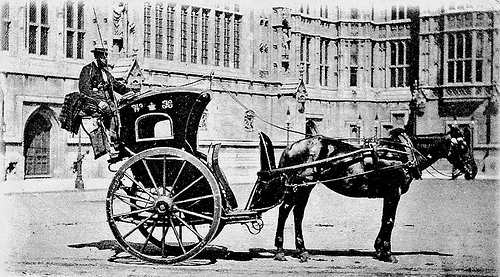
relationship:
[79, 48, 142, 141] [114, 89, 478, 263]
man riding horse carriage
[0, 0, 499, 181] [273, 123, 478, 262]
building behind brown horse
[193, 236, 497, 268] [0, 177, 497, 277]
shadow on floor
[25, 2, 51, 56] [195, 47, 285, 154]
window on wall.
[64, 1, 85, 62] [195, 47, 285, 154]
window on wall.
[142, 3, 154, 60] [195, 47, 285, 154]
window on wall.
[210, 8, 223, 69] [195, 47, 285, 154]
window on wall.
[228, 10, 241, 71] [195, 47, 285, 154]
window on wall.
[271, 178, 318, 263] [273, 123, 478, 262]
legs on brown horse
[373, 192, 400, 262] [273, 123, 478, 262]
legs on brown horse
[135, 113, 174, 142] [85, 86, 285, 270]
window on wagon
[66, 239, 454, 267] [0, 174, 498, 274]
shadow on floor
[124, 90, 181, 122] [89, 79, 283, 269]
numbers on carriage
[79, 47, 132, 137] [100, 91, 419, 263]
man sitting on carriage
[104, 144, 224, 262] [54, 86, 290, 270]
wheel on carriage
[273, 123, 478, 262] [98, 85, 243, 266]
brown horse attached to carriage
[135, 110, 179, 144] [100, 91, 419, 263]
window on carriage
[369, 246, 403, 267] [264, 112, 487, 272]
hoof on horse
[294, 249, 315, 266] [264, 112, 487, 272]
hoof on horse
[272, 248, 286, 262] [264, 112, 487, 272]
hoof on horse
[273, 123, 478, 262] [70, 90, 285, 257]
brown horse pulling carriage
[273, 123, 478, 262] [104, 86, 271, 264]
brown horse pulling carriage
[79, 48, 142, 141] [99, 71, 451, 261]
man sitting on back of carriage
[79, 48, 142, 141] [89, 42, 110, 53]
man wearing hat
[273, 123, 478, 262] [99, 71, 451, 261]
brown horse harnessed to carriage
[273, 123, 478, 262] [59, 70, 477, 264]
brown horse drawn carriage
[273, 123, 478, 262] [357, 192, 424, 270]
brown horse front legs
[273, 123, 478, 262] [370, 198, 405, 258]
brown horse front legs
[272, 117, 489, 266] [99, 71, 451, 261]
brown horse and carriage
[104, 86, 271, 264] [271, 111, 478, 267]
carriage and horse